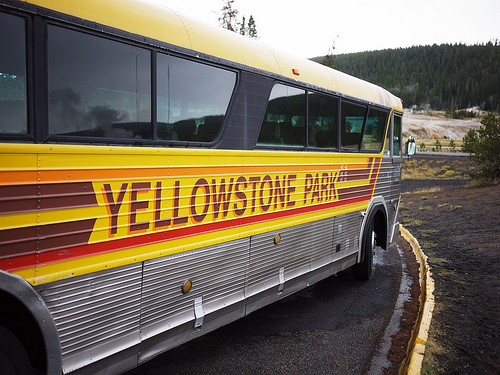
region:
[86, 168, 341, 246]
The words YELLOWSTONE PARK on bus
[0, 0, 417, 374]
bus on the street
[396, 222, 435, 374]
yellow curb on street edge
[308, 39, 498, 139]
trees on a mountain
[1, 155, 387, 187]
orange stripe on bus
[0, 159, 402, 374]
silver area on bus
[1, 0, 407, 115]
yellow top on bus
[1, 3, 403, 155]
windows along side of bus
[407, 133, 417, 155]
driver's rear view mirror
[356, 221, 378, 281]
right front wheel on bus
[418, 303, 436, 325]
a yellow curb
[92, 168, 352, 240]
writing on the bus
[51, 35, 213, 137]
windows on the bus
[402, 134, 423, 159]
a mirror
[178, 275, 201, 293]
light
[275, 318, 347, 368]
the road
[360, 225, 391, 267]
front tire of the bus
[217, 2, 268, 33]
trees in the sky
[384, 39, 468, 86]
the green bushes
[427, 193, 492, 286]
the dirt is brown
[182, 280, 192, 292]
Small yellow reflector light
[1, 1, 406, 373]
Large tourist bus on road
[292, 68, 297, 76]
Orange reflector light on bus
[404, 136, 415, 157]
Side view mirror on bus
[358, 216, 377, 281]
Black front tire on bus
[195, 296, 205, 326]
Silver metal latch on bus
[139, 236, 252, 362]
Bagge compartment door on bus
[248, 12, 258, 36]
Top of evergreen tree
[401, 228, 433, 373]
Yellow painted border on road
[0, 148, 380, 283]
Wide yellow stripe on bus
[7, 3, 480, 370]
Vintage tourist bus for the Yellowstone National Park.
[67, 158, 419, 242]
Burgundy lettering on the side of a tour bus.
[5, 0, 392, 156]
Tinted windows of a tour bus.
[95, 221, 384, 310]
Silver steel ridged siding of a tour bus.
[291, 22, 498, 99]
Mountain covered with a bank of trees.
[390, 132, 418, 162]
Rear view mirror of tour bus.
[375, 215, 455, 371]
Long yellow curb of a parking area.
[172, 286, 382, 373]
Paved cement ground of a parking area.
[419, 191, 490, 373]
Soil ground cover.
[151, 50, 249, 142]
Unique shaped tinted window of a tour bus.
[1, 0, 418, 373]
A yellow bus.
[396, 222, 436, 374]
Painted street edge.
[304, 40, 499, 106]
A mountain in the background.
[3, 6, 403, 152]
Windows on a bus.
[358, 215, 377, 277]
A front wheel of a bus.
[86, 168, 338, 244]
A sign on the body of a bus.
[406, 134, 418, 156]
A back mirror of a bus.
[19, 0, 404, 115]
Yellow roof of a bus.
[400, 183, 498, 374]
Dirt on the side of a road.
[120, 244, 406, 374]
Paved road.